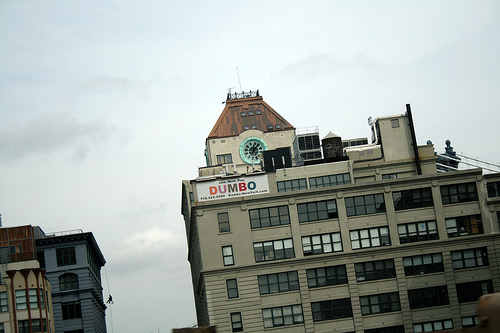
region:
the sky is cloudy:
[54, 83, 144, 211]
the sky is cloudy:
[52, 89, 135, 241]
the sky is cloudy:
[88, 145, 185, 286]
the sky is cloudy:
[113, 233, 189, 305]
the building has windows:
[182, 160, 498, 325]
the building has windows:
[185, 173, 457, 327]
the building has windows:
[196, 159, 448, 326]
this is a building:
[170, 76, 498, 329]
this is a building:
[2, 212, 120, 332]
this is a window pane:
[259, 270, 269, 286]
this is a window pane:
[278, 261, 290, 284]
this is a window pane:
[299, 225, 314, 249]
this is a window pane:
[318, 227, 329, 247]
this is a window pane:
[352, 231, 358, 244]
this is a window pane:
[359, 227, 383, 246]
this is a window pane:
[306, 229, 321, 249]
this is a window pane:
[401, 225, 420, 240]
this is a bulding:
[7, 222, 119, 324]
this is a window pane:
[217, 252, 237, 273]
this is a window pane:
[218, 225, 231, 232]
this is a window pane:
[254, 273, 266, 285]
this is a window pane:
[259, 280, 271, 297]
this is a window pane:
[287, 277, 299, 293]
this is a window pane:
[301, 231, 315, 244]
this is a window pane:
[347, 234, 363, 250]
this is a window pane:
[358, 225, 371, 239]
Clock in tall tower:
[236, 138, 268, 164]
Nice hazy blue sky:
[57, 48, 134, 115]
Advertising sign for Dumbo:
[190, 170, 276, 202]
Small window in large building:
[216, 240, 239, 267]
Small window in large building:
[209, 211, 235, 235]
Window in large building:
[243, 200, 295, 232]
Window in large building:
[296, 227, 346, 259]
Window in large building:
[301, 260, 356, 293]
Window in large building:
[397, 246, 450, 283]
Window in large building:
[51, 239, 84, 267]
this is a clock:
[235, 131, 272, 163]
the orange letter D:
[206, 176, 221, 200]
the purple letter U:
[216, 184, 228, 196]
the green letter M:
[225, 178, 240, 194]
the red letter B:
[231, 176, 248, 191]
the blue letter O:
[242, 178, 264, 197]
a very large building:
[143, 53, 499, 331]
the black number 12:
[247, 137, 253, 146]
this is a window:
[313, 223, 340, 248]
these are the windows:
[292, 214, 383, 271]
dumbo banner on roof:
[185, 163, 270, 211]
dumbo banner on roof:
[183, 160, 273, 205]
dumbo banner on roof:
[182, 162, 277, 208]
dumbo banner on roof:
[195, 161, 270, 207]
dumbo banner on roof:
[192, 165, 279, 210]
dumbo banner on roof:
[190, 163, 272, 209]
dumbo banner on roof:
[186, 164, 269, 205]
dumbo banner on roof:
[194, 161, 274, 211]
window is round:
[240, 137, 267, 165]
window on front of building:
[214, 209, 233, 239]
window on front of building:
[218, 245, 236, 269]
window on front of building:
[223, 277, 240, 300]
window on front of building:
[228, 308, 244, 332]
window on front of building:
[58, 270, 79, 292]